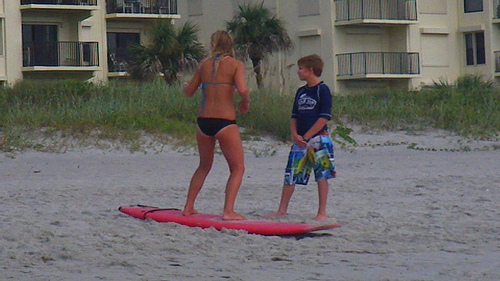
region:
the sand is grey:
[64, 63, 231, 244]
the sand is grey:
[1, 112, 200, 276]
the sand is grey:
[20, 129, 135, 269]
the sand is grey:
[86, 198, 160, 276]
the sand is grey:
[61, 134, 165, 279]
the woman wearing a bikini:
[118, 22, 339, 239]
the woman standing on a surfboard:
[100, 33, 340, 244]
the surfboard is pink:
[115, 192, 342, 256]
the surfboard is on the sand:
[111, 195, 343, 245]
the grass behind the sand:
[3, 80, 191, 151]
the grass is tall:
[7, 84, 156, 134]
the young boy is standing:
[266, 51, 355, 219]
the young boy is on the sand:
[258, 45, 360, 224]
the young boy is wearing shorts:
[256, 50, 366, 222]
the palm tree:
[215, 4, 287, 139]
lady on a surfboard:
[110, 25, 292, 270]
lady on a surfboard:
[192, 22, 343, 272]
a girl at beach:
[183, 34, 243, 227]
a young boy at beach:
[274, 49, 343, 222]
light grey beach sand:
[6, 146, 496, 276]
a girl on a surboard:
[120, 26, 337, 239]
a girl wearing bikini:
[172, 29, 251, 219]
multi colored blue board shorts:
[278, 134, 336, 184]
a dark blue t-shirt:
[284, 79, 331, 139]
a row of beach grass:
[3, 82, 491, 144]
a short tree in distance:
[217, 7, 286, 87]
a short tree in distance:
[117, 21, 212, 89]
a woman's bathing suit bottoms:
[197, 115, 243, 137]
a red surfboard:
[113, 197, 340, 238]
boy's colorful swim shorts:
[282, 133, 339, 187]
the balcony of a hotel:
[16, 37, 103, 73]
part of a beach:
[336, 147, 498, 278]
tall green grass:
[0, 81, 196, 137]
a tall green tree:
[221, 4, 296, 96]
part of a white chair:
[111, 0, 136, 12]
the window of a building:
[460, 32, 491, 67]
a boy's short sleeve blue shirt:
[287, 80, 334, 141]